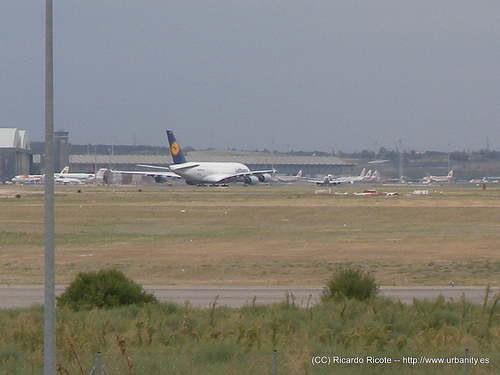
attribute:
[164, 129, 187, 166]
tail — yellow, blue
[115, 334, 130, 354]
weed — brown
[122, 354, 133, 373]
weed — brown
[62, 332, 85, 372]
weed — brown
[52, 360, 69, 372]
weed — brown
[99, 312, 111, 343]
weed — brown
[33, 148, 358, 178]
airport terminal — elongated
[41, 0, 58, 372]
lamp post — metal, tall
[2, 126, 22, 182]
airplane hangar — ovular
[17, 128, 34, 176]
airplane hangar — ovular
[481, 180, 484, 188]
fire hydrant — white, red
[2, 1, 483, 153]
sky — cloudless, blue, overcast, hazy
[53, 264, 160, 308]
shrubbery — green, overgrown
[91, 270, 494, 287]
runway — long,tan and dirt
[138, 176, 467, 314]
road — tan 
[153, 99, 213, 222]
circular — yellow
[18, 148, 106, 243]
window — large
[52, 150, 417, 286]
building — silver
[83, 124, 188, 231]
wing — white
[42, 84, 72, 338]
pole — long and silver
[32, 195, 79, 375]
pole — gray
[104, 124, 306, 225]
plane — white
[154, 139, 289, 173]
airplane — white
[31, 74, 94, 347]
pole — silver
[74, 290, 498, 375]
bushes — green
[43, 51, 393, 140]
sky —  dark and grey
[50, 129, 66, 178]
control tower — airport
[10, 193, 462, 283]
field — of brown grass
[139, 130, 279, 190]
airplane — sitting on field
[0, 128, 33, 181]
hangers — for the airplanes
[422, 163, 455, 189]
airplane — taking off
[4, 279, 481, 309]
service road — by the airport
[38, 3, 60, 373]
light pole — by the road